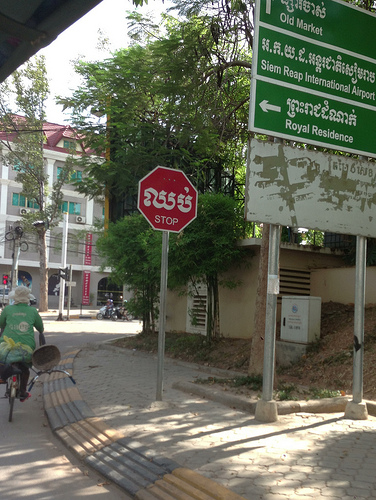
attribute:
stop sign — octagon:
[136, 164, 199, 232]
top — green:
[0, 306, 49, 362]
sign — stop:
[135, 162, 200, 234]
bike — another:
[14, 329, 82, 399]